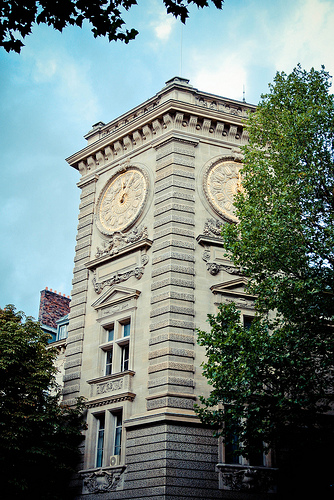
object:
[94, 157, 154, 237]
clock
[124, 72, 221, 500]
tower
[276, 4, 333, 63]
sky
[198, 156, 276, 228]
clock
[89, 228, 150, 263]
decorations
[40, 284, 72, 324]
chimney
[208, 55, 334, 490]
tree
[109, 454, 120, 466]
fan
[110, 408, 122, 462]
window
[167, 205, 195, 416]
ribbed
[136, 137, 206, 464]
structure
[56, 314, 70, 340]
square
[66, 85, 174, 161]
roof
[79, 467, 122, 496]
design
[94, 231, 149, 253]
decorative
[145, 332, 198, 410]
part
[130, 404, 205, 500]
building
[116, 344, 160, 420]
side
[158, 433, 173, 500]
edge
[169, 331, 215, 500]
wall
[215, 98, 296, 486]
building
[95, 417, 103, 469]
curtains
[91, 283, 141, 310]
triangle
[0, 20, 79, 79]
sky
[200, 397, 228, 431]
leaves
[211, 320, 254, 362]
branch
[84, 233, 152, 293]
decorative area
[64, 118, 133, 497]
building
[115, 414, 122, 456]
window curtain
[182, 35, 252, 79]
clouds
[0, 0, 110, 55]
tree's leaves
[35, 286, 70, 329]
chimney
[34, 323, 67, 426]
building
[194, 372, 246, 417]
leaves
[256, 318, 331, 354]
branch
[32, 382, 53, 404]
leaves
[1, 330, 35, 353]
branch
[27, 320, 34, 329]
leaves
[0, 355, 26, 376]
branch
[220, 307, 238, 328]
leaves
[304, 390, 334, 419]
branch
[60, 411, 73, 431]
leaves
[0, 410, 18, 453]
branch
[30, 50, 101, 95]
clouds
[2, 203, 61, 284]
sky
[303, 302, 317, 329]
leaves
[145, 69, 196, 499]
corner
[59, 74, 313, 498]
clock tower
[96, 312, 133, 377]
windows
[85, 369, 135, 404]
balcony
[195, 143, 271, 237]
clock face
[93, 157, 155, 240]
clock face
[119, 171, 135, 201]
hands